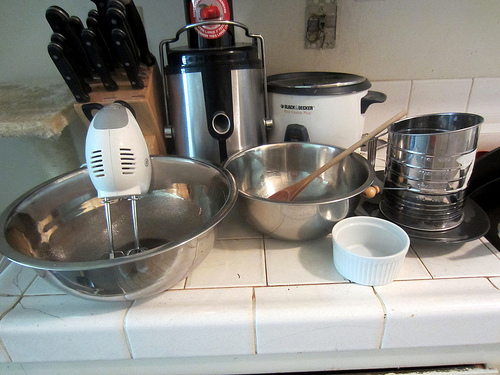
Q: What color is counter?
A: White.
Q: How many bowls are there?
A: Two.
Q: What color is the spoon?
A: Brown.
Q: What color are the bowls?
A: Silver.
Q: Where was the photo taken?
A: On the counter.